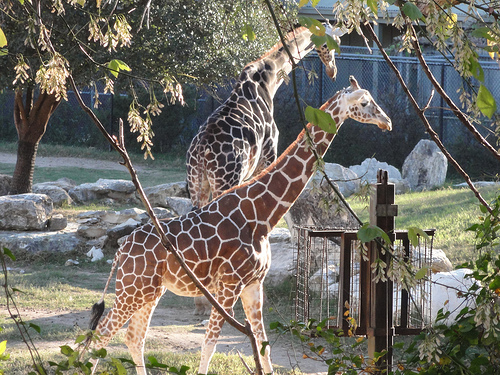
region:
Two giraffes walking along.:
[78, 5, 385, 366]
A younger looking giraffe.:
[191, 83, 389, 354]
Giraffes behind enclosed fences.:
[103, 17, 463, 187]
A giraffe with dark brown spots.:
[181, 13, 343, 113]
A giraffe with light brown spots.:
[131, 140, 296, 330]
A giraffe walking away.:
[185, 27, 294, 192]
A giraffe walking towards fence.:
[151, 23, 339, 150]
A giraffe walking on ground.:
[86, 283, 326, 360]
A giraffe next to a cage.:
[221, 140, 476, 348]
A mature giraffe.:
[141, 24, 288, 196]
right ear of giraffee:
[341, 80, 376, 105]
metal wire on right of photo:
[296, 222, 338, 330]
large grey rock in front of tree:
[7, 182, 64, 242]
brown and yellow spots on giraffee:
[186, 216, 248, 272]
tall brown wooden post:
[353, 166, 415, 364]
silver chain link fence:
[390, 57, 482, 147]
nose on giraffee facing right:
[373, 95, 398, 147]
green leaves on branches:
[170, 6, 226, 72]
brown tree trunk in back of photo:
[13, 110, 48, 190]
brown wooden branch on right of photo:
[402, 75, 482, 197]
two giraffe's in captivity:
[73, 14, 424, 374]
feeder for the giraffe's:
[288, 173, 462, 373]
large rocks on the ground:
[3, 140, 476, 232]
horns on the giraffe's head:
[349, 71, 359, 89]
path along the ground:
[1, 144, 183, 178]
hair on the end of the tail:
[78, 289, 110, 357]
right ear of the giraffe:
[346, 82, 374, 107]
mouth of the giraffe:
[376, 120, 393, 137]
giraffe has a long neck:
[253, 88, 340, 228]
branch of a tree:
[53, 46, 280, 372]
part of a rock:
[429, 180, 439, 200]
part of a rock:
[38, 206, 47, 221]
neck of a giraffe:
[275, 197, 283, 214]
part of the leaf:
[465, 320, 475, 345]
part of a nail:
[342, 257, 354, 292]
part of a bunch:
[438, 306, 453, 342]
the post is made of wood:
[368, 179, 392, 374]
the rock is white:
[418, 267, 498, 324]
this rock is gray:
[2, 197, 68, 232]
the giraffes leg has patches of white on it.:
[244, 291, 276, 374]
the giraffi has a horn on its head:
[341, 72, 361, 90]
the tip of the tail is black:
[81, 237, 130, 357]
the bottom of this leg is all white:
[193, 340, 218, 373]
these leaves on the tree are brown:
[33, 49, 79, 96]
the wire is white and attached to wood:
[293, 227, 346, 334]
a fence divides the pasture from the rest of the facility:
[301, 50, 497, 167]